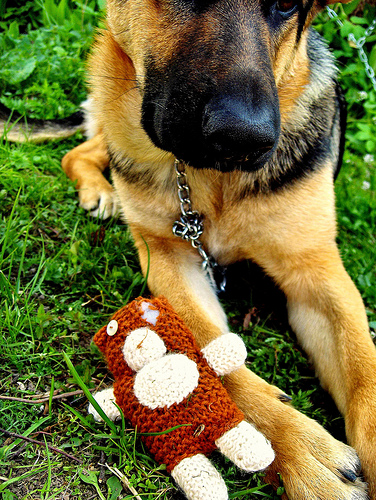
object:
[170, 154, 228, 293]
chain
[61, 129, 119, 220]
leg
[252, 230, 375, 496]
leg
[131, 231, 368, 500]
leg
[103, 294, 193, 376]
doll face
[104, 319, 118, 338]
button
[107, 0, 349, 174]
face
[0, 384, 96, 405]
stick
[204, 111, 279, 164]
nose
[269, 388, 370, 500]
paw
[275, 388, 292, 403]
toenail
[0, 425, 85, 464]
sticks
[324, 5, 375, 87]
chain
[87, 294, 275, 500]
yarn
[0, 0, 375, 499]
yard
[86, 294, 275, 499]
doll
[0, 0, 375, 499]
dog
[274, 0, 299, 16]
eye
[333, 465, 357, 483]
nail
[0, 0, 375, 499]
grass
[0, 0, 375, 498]
ground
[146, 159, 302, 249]
chest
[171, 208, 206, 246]
knot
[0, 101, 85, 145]
dog tail